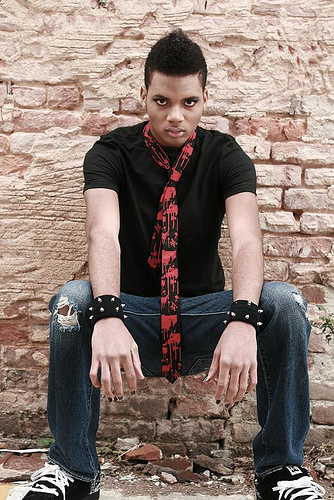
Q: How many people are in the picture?
A: One.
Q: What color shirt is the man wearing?
A: Black.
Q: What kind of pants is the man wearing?
A: Jeans.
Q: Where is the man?
A: Against the wall.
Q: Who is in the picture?
A: The man.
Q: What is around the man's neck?
A: A tie.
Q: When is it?
A: Day time.